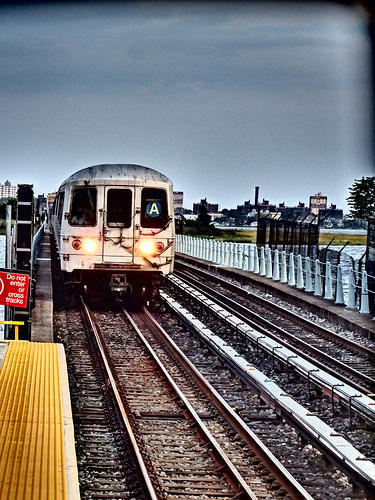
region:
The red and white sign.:
[2, 269, 27, 311]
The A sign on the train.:
[146, 200, 164, 219]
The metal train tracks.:
[68, 301, 370, 497]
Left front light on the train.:
[84, 239, 99, 256]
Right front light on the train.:
[138, 240, 153, 263]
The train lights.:
[81, 235, 152, 253]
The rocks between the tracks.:
[156, 435, 199, 493]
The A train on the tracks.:
[45, 157, 173, 270]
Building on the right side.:
[305, 190, 347, 228]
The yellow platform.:
[4, 336, 59, 497]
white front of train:
[66, 167, 167, 292]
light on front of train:
[144, 236, 165, 256]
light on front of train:
[64, 231, 104, 267]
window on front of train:
[70, 179, 102, 230]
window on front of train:
[107, 185, 131, 238]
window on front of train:
[137, 183, 167, 233]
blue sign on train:
[147, 197, 160, 217]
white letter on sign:
[148, 197, 161, 216]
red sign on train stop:
[0, 273, 30, 318]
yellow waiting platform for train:
[1, 339, 57, 433]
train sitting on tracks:
[17, 157, 366, 454]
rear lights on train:
[62, 230, 177, 262]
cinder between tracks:
[71, 292, 372, 491]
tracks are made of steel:
[60, 296, 373, 493]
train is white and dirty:
[58, 159, 189, 288]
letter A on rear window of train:
[144, 196, 170, 226]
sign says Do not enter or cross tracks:
[0, 264, 35, 313]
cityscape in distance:
[1, 165, 374, 234]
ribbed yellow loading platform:
[0, 340, 76, 496]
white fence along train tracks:
[175, 234, 373, 313]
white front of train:
[56, 163, 173, 286]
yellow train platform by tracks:
[6, 344, 56, 422]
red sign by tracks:
[0, 275, 33, 323]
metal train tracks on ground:
[108, 353, 194, 445]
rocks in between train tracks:
[110, 355, 177, 433]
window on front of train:
[106, 190, 131, 231]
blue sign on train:
[144, 201, 164, 221]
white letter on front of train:
[147, 202, 159, 219]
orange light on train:
[140, 242, 163, 258]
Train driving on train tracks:
[47, 158, 175, 309]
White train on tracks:
[49, 163, 177, 304]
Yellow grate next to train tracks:
[0, 339, 67, 497]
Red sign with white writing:
[0, 270, 29, 308]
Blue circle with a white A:
[143, 198, 162, 219]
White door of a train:
[100, 183, 136, 265]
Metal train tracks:
[77, 249, 373, 498]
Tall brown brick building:
[306, 187, 329, 218]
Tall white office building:
[1, 178, 17, 202]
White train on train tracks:
[46, 162, 177, 309]